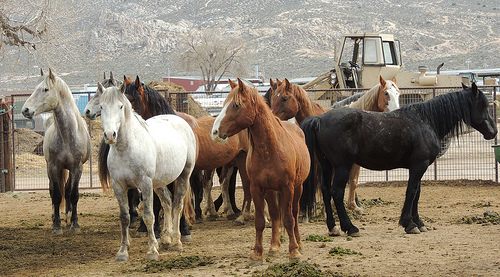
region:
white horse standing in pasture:
[94, 87, 191, 271]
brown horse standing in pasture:
[218, 81, 324, 259]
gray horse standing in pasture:
[23, 64, 97, 241]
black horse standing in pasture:
[316, 92, 498, 264]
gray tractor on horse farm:
[301, 11, 481, 117]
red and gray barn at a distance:
[156, 46, 247, 116]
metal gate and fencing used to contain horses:
[0, 78, 498, 163]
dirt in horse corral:
[108, 201, 414, 276]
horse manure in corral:
[125, 226, 440, 271]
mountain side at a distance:
[84, 11, 488, 73]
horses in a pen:
[8, 67, 499, 256]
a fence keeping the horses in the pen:
[9, 75, 498, 200]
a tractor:
[300, 16, 492, 141]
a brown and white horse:
[211, 39, 314, 236]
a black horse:
[302, 92, 493, 214]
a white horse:
[78, 85, 250, 270]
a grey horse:
[18, 74, 112, 211]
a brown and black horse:
[120, 76, 254, 173]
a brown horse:
[268, 71, 345, 153]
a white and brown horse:
[321, 77, 447, 146]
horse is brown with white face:
[200, 71, 350, 274]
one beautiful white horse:
[88, 75, 193, 268]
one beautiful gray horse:
[2, 65, 87, 256]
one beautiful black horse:
[280, 76, 490, 256]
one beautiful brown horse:
[204, 67, 316, 274]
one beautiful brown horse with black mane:
[119, 66, 257, 221]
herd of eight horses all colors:
[1, 64, 481, 244]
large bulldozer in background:
[293, 33, 443, 129]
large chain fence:
[23, 56, 487, 213]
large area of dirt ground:
[20, 200, 476, 267]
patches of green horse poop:
[120, 202, 458, 267]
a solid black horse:
[297, 85, 495, 242]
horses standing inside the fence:
[7, 56, 494, 266]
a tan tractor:
[277, 24, 473, 139]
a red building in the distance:
[159, 66, 265, 94]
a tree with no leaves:
[167, 21, 249, 103]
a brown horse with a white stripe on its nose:
[197, 74, 327, 274]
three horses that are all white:
[9, 63, 206, 266]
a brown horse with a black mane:
[119, 68, 251, 220]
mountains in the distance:
[80, 1, 322, 74]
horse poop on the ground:
[125, 244, 367, 274]